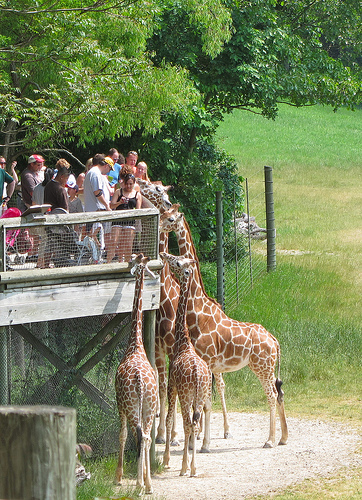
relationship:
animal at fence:
[111, 252, 160, 496] [1, 208, 161, 460]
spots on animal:
[219, 324, 249, 355] [111, 252, 160, 496]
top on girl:
[108, 185, 146, 220] [37, 159, 84, 269]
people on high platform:
[0, 147, 145, 248] [0, 194, 159, 325]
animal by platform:
[111, 252, 160, 496] [0, 194, 162, 471]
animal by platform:
[158, 249, 213, 480] [0, 194, 162, 471]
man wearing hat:
[19, 154, 41, 261] [25, 153, 45, 163]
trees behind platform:
[128, 85, 254, 275] [0, 207, 177, 329]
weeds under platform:
[259, 207, 343, 332] [0, 207, 177, 329]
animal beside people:
[111, 252, 160, 496] [11, 151, 149, 248]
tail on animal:
[273, 345, 284, 404] [158, 201, 290, 452]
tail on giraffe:
[188, 365, 202, 424] [154, 248, 215, 480]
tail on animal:
[132, 371, 146, 457] [111, 252, 160, 496]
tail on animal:
[192, 365, 202, 425] [158, 249, 213, 480]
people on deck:
[2, 148, 158, 260] [0, 204, 167, 325]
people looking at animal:
[2, 148, 158, 260] [111, 252, 160, 496]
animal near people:
[158, 201, 290, 452] [108, 174, 143, 263]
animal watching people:
[111, 252, 160, 496] [2, 148, 158, 260]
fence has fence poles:
[1, 165, 274, 461] [263, 165, 276, 270]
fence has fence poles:
[1, 165, 274, 461] [244, 177, 253, 289]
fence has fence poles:
[1, 165, 274, 461] [231, 189, 240, 304]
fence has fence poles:
[1, 165, 274, 461] [213, 190, 223, 313]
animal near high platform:
[111, 252, 160, 496] [1, 194, 159, 448]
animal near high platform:
[158, 249, 213, 480] [1, 194, 159, 448]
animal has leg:
[158, 201, 290, 452] [212, 373, 228, 437]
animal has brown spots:
[111, 252, 160, 496] [121, 365, 137, 396]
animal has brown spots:
[158, 250, 213, 480] [178, 358, 192, 380]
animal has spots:
[158, 202, 291, 451] [219, 324, 249, 355]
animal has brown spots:
[139, 176, 196, 443] [164, 283, 177, 305]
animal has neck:
[111, 252, 160, 496] [129, 268, 143, 342]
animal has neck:
[158, 249, 213, 480] [174, 272, 191, 345]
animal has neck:
[158, 201, 290, 452] [172, 227, 203, 294]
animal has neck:
[137, 175, 196, 443] [151, 200, 169, 271]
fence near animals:
[1, 208, 161, 460] [138, 175, 231, 445]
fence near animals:
[1, 208, 161, 460] [158, 200, 288, 447]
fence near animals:
[1, 208, 161, 460] [156, 250, 214, 479]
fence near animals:
[1, 208, 161, 460] [112, 249, 161, 494]